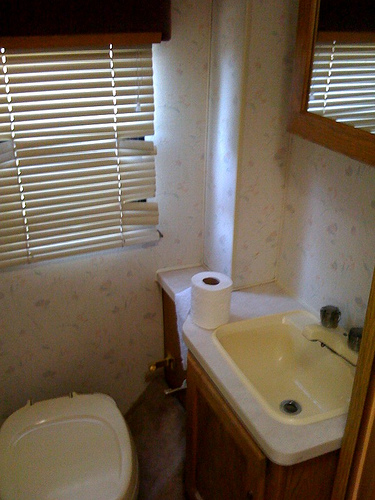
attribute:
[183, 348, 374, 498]
cabinet — wooden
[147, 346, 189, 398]
bar — metal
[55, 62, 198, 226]
sunlight — shining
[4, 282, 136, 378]
wallpaper — patterned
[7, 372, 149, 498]
lid — white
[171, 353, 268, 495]
door — wooden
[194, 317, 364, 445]
sink — white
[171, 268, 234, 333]
toilet paper — white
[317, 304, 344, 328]
handle — grey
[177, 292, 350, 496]
sink — wooden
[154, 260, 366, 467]
counter — linoleum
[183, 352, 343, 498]
cupboard — brown